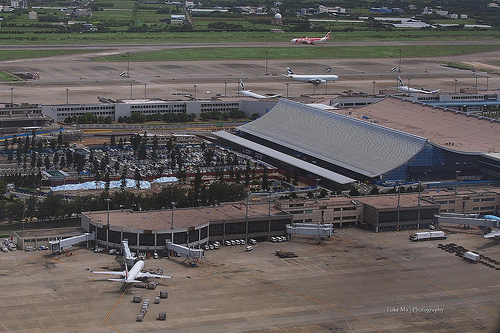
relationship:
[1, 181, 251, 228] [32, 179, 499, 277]
trees along back of airport terminal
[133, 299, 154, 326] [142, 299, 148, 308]
luggage car carrying luggage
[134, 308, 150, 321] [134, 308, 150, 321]
luggage car of luggage car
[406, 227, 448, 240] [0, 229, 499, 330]
truck on tarmac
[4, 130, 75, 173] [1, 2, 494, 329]
trees at airport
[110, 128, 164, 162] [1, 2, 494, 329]
trees at airport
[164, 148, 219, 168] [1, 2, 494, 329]
trees at airport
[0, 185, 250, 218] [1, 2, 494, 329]
trees at airport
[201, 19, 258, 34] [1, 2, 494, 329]
trees at airport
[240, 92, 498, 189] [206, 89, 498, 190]
roof at airport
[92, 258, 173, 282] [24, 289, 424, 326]
airplane on runway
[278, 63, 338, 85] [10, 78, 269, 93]
white plane on runway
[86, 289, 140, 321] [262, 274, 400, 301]
line on ground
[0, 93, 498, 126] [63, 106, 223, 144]
airport terminal for airport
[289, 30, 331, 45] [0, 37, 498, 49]
plane on runway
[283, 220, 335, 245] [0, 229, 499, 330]
tunnel on tarmac